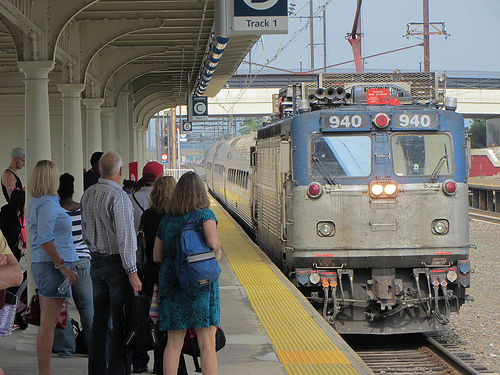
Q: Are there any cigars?
A: No, there are no cigars.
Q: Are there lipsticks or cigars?
A: No, there are no cigars or lipsticks.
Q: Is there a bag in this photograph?
A: Yes, there is a bag.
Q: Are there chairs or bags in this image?
A: Yes, there is a bag.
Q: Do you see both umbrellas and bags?
A: No, there is a bag but no umbrellas.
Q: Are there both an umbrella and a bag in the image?
A: No, there is a bag but no umbrellas.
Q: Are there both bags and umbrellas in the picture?
A: No, there is a bag but no umbrellas.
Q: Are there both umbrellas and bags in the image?
A: No, there is a bag but no umbrellas.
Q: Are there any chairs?
A: No, there are no chairs.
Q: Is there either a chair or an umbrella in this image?
A: No, there are no chairs or umbrellas.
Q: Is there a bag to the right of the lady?
A: Yes, there is a bag to the right of the lady.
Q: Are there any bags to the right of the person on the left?
A: Yes, there is a bag to the right of the lady.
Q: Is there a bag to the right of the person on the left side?
A: Yes, there is a bag to the right of the lady.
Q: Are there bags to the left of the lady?
A: No, the bag is to the right of the lady.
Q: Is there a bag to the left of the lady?
A: No, the bag is to the right of the lady.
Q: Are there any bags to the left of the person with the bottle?
A: No, the bag is to the right of the lady.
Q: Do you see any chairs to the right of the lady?
A: No, there is a bag to the right of the lady.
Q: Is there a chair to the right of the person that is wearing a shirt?
A: No, there is a bag to the right of the lady.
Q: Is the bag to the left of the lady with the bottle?
A: No, the bag is to the right of the lady.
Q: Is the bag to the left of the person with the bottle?
A: No, the bag is to the right of the lady.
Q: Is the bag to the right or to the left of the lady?
A: The bag is to the right of the lady.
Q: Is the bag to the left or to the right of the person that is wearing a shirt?
A: The bag is to the right of the lady.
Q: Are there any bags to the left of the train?
A: Yes, there is a bag to the left of the train.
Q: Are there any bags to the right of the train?
A: No, the bag is to the left of the train.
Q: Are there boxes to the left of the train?
A: No, there is a bag to the left of the train.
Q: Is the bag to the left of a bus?
A: No, the bag is to the left of the train.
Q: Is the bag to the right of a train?
A: No, the bag is to the left of a train.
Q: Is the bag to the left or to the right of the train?
A: The bag is to the left of the train.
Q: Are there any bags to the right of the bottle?
A: Yes, there is a bag to the right of the bottle.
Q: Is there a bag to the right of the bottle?
A: Yes, there is a bag to the right of the bottle.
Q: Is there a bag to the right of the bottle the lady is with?
A: Yes, there is a bag to the right of the bottle.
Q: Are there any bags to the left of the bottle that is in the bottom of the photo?
A: No, the bag is to the right of the bottle.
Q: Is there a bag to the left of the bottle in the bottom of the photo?
A: No, the bag is to the right of the bottle.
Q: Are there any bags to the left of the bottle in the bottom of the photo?
A: No, the bag is to the right of the bottle.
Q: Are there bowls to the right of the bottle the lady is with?
A: No, there is a bag to the right of the bottle.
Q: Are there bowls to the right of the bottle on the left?
A: No, there is a bag to the right of the bottle.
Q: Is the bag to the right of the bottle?
A: Yes, the bag is to the right of the bottle.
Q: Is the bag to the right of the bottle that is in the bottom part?
A: Yes, the bag is to the right of the bottle.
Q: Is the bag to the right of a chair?
A: No, the bag is to the right of the bottle.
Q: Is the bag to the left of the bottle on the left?
A: No, the bag is to the right of the bottle.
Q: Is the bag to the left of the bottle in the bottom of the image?
A: No, the bag is to the right of the bottle.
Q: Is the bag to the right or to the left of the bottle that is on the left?
A: The bag is to the right of the bottle.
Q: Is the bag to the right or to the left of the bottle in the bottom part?
A: The bag is to the right of the bottle.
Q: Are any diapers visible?
A: No, there are no diapers.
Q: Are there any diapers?
A: No, there are no diapers.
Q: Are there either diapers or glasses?
A: No, there are no diapers or glasses.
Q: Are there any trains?
A: Yes, there is a train.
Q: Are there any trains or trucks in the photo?
A: Yes, there is a train.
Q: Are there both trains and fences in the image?
A: No, there is a train but no fences.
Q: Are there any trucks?
A: No, there are no trucks.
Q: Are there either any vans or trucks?
A: No, there are no trucks or vans.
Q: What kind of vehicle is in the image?
A: The vehicle is a train.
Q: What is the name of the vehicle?
A: The vehicle is a train.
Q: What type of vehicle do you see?
A: The vehicle is a train.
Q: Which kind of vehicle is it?
A: The vehicle is a train.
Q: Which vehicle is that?
A: This is a train.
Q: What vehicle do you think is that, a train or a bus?
A: This is a train.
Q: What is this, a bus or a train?
A: This is a train.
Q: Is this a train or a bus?
A: This is a train.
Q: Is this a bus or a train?
A: This is a train.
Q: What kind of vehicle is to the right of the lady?
A: The vehicle is a train.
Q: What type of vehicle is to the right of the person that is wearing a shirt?
A: The vehicle is a train.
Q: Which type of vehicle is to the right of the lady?
A: The vehicle is a train.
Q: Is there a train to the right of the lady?
A: Yes, there is a train to the right of the lady.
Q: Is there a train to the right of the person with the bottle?
A: Yes, there is a train to the right of the lady.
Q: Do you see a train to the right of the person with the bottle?
A: Yes, there is a train to the right of the lady.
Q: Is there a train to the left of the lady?
A: No, the train is to the right of the lady.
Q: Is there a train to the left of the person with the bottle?
A: No, the train is to the right of the lady.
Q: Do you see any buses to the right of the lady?
A: No, there is a train to the right of the lady.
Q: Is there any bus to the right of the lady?
A: No, there is a train to the right of the lady.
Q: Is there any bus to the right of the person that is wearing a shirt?
A: No, there is a train to the right of the lady.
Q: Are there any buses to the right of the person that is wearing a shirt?
A: No, there is a train to the right of the lady.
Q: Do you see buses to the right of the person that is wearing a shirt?
A: No, there is a train to the right of the lady.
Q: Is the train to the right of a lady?
A: Yes, the train is to the right of a lady.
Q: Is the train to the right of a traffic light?
A: No, the train is to the right of a lady.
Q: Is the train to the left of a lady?
A: No, the train is to the right of a lady.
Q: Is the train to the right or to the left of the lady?
A: The train is to the right of the lady.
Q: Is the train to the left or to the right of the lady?
A: The train is to the right of the lady.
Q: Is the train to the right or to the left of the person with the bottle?
A: The train is to the right of the lady.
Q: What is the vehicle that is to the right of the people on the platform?
A: The vehicle is a train.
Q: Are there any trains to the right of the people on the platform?
A: Yes, there is a train to the right of the people.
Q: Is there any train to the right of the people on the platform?
A: Yes, there is a train to the right of the people.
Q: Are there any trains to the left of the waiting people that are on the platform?
A: No, the train is to the right of the people.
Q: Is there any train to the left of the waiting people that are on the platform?
A: No, the train is to the right of the people.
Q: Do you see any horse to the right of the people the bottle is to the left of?
A: No, there is a train to the right of the people.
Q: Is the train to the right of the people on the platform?
A: Yes, the train is to the right of the people.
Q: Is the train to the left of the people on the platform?
A: No, the train is to the right of the people.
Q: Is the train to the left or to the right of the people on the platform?
A: The train is to the right of the people.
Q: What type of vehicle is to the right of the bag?
A: The vehicle is a train.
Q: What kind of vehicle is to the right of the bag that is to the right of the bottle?
A: The vehicle is a train.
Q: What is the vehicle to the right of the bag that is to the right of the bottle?
A: The vehicle is a train.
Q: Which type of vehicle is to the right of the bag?
A: The vehicle is a train.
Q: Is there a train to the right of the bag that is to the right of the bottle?
A: Yes, there is a train to the right of the bag.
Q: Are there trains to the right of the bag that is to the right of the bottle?
A: Yes, there is a train to the right of the bag.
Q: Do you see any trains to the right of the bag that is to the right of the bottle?
A: Yes, there is a train to the right of the bag.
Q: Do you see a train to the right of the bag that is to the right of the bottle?
A: Yes, there is a train to the right of the bag.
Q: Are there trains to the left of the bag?
A: No, the train is to the right of the bag.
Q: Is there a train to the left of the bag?
A: No, the train is to the right of the bag.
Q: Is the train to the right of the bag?
A: Yes, the train is to the right of the bag.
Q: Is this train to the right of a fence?
A: No, the train is to the right of the bag.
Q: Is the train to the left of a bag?
A: No, the train is to the right of a bag.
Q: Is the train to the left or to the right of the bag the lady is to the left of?
A: The train is to the right of the bag.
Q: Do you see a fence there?
A: No, there are no fences.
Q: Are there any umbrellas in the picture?
A: No, there are no umbrellas.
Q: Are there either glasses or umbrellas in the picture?
A: No, there are no umbrellas or glasses.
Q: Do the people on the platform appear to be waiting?
A: Yes, the people are waiting.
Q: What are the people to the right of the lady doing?
A: The people are waiting.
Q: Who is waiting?
A: The people are waiting.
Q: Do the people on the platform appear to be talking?
A: No, the people are waiting.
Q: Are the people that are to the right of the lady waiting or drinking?
A: The people are waiting.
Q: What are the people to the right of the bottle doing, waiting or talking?
A: The people are waiting.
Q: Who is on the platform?
A: The people are on the platform.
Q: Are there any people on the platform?
A: Yes, there are people on the platform.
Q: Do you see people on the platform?
A: Yes, there are people on the platform.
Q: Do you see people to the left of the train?
A: Yes, there are people to the left of the train.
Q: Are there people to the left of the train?
A: Yes, there are people to the left of the train.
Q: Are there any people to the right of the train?
A: No, the people are to the left of the train.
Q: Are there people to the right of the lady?
A: Yes, there are people to the right of the lady.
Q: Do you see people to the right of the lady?
A: Yes, there are people to the right of the lady.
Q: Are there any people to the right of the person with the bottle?
A: Yes, there are people to the right of the lady.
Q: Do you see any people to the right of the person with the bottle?
A: Yes, there are people to the right of the lady.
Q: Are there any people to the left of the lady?
A: No, the people are to the right of the lady.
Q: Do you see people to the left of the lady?
A: No, the people are to the right of the lady.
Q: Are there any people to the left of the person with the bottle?
A: No, the people are to the right of the lady.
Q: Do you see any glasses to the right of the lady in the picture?
A: No, there are people to the right of the lady.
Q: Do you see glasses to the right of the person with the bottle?
A: No, there are people to the right of the lady.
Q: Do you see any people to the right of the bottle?
A: Yes, there are people to the right of the bottle.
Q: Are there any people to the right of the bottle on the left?
A: Yes, there are people to the right of the bottle.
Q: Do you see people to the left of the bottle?
A: No, the people are to the right of the bottle.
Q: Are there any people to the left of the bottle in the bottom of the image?
A: No, the people are to the right of the bottle.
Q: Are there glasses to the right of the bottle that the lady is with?
A: No, there are people to the right of the bottle.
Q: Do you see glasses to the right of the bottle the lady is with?
A: No, there are people to the right of the bottle.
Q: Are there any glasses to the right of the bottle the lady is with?
A: No, there are people to the right of the bottle.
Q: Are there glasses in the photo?
A: No, there are no glasses.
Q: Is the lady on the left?
A: Yes, the lady is on the left of the image.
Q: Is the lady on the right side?
A: No, the lady is on the left of the image.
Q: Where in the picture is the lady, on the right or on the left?
A: The lady is on the left of the image.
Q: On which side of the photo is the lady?
A: The lady is on the left of the image.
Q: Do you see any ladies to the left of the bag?
A: Yes, there is a lady to the left of the bag.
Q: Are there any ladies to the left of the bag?
A: Yes, there is a lady to the left of the bag.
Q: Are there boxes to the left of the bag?
A: No, there is a lady to the left of the bag.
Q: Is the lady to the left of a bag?
A: Yes, the lady is to the left of a bag.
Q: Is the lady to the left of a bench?
A: No, the lady is to the left of a bag.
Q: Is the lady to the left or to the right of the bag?
A: The lady is to the left of the bag.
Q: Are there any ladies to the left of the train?
A: Yes, there is a lady to the left of the train.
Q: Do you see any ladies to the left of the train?
A: Yes, there is a lady to the left of the train.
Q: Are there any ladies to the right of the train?
A: No, the lady is to the left of the train.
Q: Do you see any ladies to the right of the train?
A: No, the lady is to the left of the train.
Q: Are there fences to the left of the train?
A: No, there is a lady to the left of the train.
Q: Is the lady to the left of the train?
A: Yes, the lady is to the left of the train.